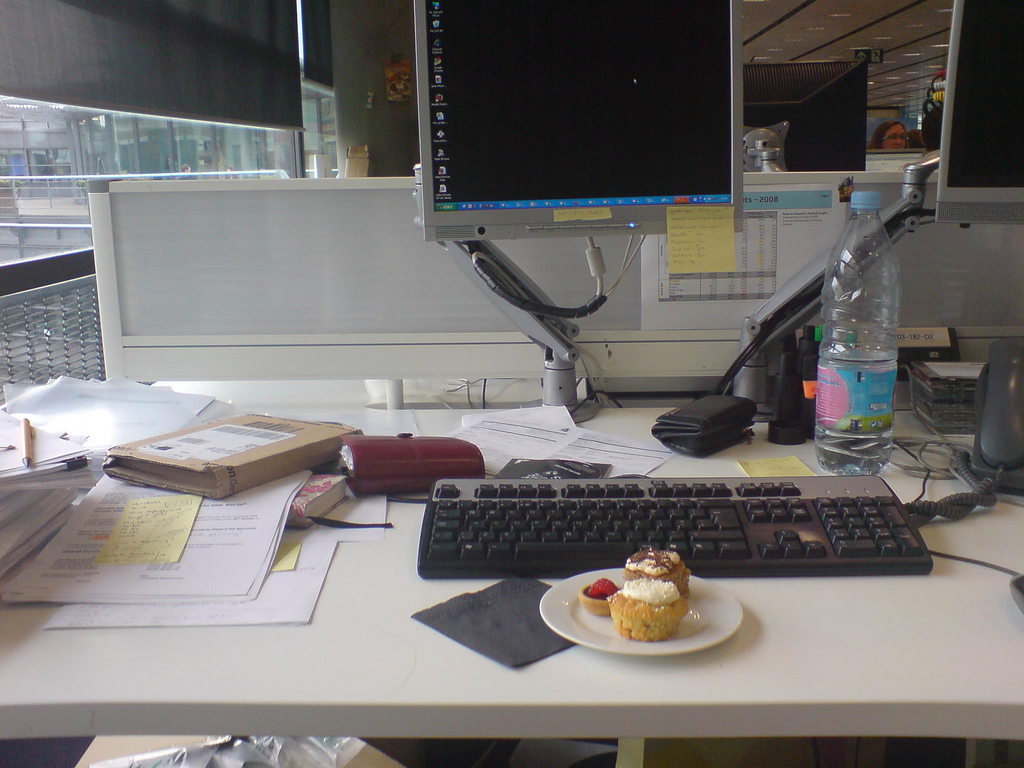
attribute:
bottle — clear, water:
[814, 180, 910, 468]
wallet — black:
[647, 389, 760, 457]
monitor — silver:
[357, 203, 455, 247]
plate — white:
[501, 539, 756, 673]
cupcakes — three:
[568, 532, 692, 630]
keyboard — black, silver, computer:
[404, 441, 936, 586]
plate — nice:
[544, 569, 739, 662]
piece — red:
[583, 579, 614, 595]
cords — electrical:
[423, 234, 672, 444]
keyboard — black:
[416, 456, 948, 565]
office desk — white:
[77, 402, 981, 714]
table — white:
[86, 513, 938, 762]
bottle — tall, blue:
[809, 169, 993, 591]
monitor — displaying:
[385, 24, 822, 284]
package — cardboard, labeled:
[96, 374, 384, 476]